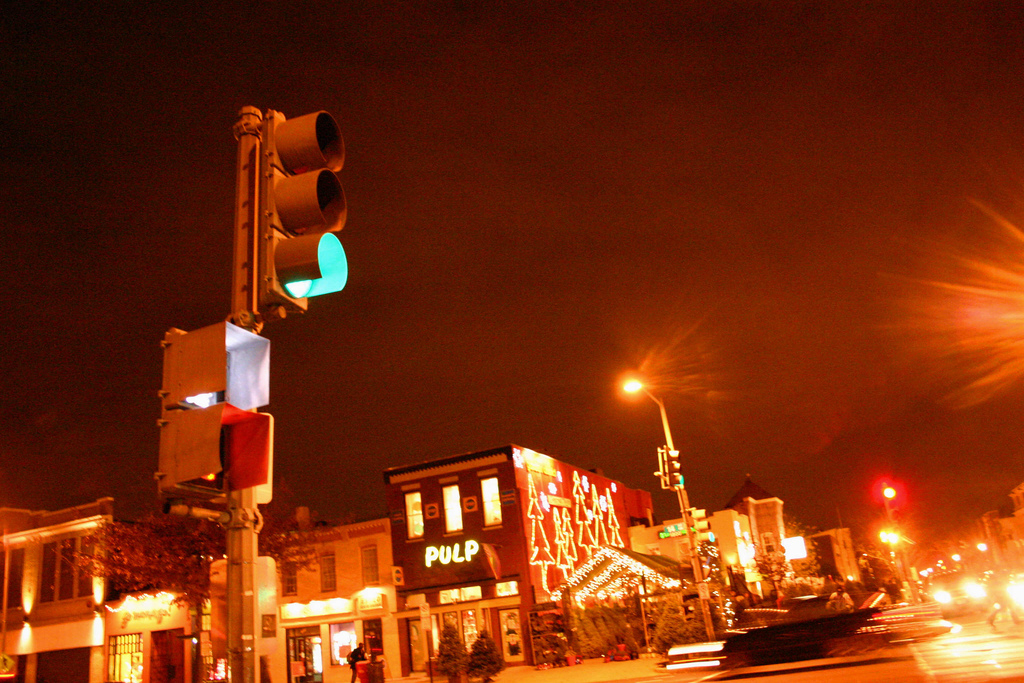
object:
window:
[403, 490, 423, 543]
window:
[441, 484, 465, 535]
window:
[479, 476, 503, 529]